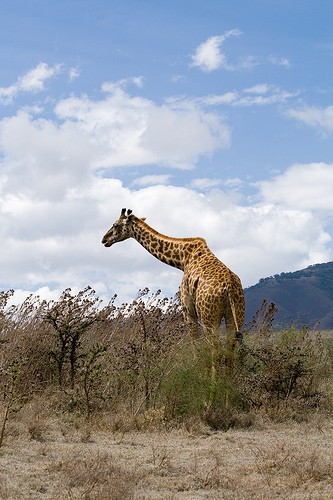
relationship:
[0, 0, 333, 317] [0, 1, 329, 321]
cloud in sky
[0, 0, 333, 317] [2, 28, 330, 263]
cloud in sky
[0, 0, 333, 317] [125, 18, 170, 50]
cloud in sky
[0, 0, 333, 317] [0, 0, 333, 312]
cloud in blue sky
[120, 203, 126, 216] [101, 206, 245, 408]
horn of giraffe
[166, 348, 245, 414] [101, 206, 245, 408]
brush behind giraffe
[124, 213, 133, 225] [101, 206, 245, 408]
ear of giraffe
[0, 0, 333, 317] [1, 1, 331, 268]
cloud in sky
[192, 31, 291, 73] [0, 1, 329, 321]
cloud in sky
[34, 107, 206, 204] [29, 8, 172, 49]
white clouds in blue sky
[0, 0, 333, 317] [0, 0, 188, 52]
cloud in sky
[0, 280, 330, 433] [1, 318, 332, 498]
weeds in field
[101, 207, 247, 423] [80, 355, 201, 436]
giraffe in field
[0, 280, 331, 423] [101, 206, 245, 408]
weeds in giraffe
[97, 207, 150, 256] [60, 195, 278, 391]
head of giraffe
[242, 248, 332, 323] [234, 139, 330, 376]
hill in distance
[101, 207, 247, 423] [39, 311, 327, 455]
giraffe in field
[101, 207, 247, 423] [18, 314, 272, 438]
giraffe in field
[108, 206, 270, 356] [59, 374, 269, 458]
giraffe walking in field